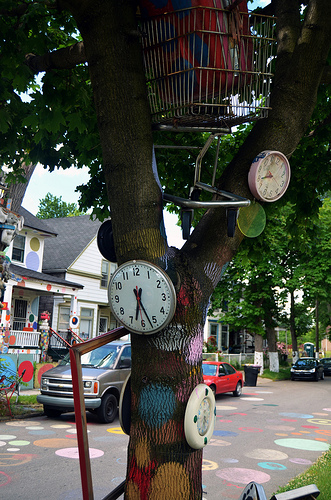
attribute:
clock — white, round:
[102, 259, 173, 329]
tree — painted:
[129, 182, 212, 287]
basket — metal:
[136, 12, 236, 154]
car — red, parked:
[208, 354, 237, 407]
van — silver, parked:
[82, 339, 136, 431]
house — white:
[63, 220, 106, 317]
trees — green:
[19, 29, 73, 143]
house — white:
[14, 225, 53, 341]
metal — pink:
[252, 166, 262, 206]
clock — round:
[257, 143, 299, 228]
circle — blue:
[142, 375, 180, 438]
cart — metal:
[148, 133, 231, 217]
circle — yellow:
[222, 203, 275, 237]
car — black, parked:
[286, 355, 330, 390]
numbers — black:
[155, 282, 165, 324]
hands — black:
[131, 293, 154, 330]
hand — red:
[132, 289, 144, 329]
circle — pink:
[184, 330, 213, 362]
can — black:
[241, 351, 261, 385]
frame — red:
[70, 344, 132, 495]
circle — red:
[173, 277, 205, 322]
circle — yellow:
[145, 461, 194, 499]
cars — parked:
[202, 357, 320, 403]